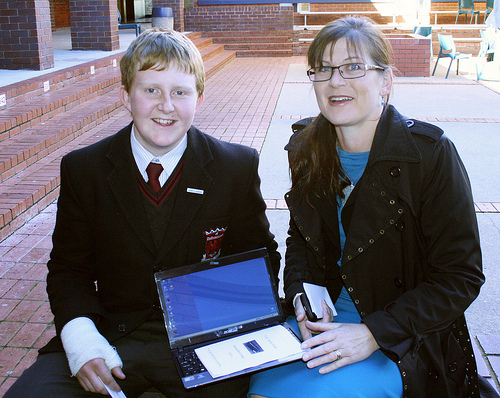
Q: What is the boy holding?
A: A laptop computer.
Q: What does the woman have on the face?
A: Eyeglasses.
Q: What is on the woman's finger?
A: A ring.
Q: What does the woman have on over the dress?
A: A jacket.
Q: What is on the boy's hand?
A: A cast.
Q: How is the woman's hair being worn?
A: In a ponytail.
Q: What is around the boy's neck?
A: A tie.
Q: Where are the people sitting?
A: In a courtyard.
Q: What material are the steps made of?
A: Brick.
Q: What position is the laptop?
A: Open.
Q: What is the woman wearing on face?
A: Glasses.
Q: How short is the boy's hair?
A: Down to the middle of his forehead.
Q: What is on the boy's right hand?
A: A cast.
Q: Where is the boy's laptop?
A: On his lap.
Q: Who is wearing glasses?
A: Woman in blue.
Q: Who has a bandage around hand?
A: Boy with Ipad.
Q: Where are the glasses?
A: On woman's face.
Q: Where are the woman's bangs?
A: Over forehead.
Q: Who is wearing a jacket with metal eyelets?
A: Woman in blue.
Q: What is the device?
A: Laptop.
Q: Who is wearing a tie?
A: Boy in jacket.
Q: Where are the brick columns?
A: Behind boy.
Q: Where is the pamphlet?
A: On laptop.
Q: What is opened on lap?
A: Laptop.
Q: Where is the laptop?
A: On the boy's lap.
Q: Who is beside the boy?
A: A woman.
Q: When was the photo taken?
A: Daytime.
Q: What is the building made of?
A: Brick.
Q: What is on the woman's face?
A: Glasses.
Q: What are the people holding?
A: Laptop.